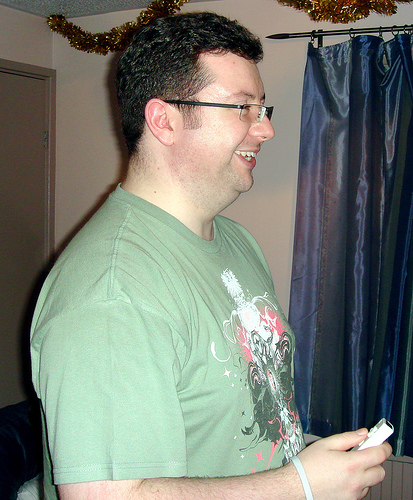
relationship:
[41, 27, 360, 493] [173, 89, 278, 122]
man wearing glasses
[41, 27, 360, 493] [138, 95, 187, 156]
man has ear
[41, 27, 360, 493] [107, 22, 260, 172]
man has head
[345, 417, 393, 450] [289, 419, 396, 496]
controller in hand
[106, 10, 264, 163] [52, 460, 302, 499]
hair on arm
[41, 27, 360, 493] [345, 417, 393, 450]
man plays controller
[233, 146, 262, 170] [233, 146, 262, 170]
mouth in mouth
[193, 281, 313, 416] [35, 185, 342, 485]
design on shirt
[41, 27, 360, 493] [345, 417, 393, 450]
man playing a controller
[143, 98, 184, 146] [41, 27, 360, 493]
ear of a man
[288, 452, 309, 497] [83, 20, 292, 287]
strap wrist of man